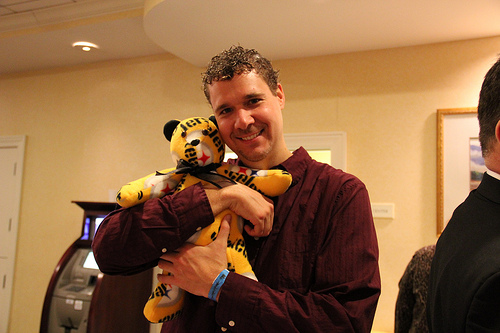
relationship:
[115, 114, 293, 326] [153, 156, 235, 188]
teddy bear has black ribbon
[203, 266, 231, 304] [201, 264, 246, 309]
blue band around man's wrist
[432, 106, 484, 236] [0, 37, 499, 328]
picture on wall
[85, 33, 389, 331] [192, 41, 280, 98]
man has hair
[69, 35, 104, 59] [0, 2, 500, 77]
light on ceiling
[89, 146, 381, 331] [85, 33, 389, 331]
shirt of man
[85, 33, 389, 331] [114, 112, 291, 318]
man holding bear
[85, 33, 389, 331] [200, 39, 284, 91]
man has curly hair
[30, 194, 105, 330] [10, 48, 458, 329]
teller machine against wall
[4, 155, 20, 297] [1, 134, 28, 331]
silver hinges on door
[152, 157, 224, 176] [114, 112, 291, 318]
lace bow on bear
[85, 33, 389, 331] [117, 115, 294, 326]
man holding stuffed animal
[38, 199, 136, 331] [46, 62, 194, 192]
atm machine along wall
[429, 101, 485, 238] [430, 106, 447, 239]
art print framed in brown wood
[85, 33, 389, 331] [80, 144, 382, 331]
man wearing maroon shirt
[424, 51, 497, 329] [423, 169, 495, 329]
man wearing jacket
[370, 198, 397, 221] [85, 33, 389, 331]
thermostat behind man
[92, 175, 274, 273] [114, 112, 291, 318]
right arm across bear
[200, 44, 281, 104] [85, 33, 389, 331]
hair on man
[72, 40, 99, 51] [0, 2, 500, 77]
light on ceiling